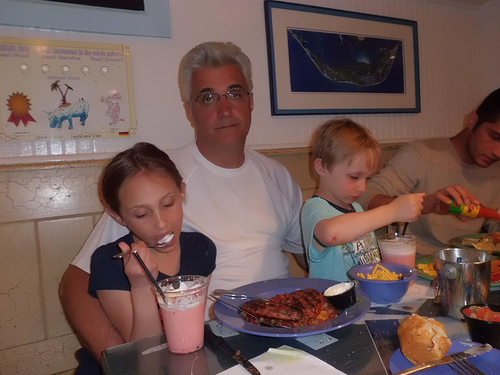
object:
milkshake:
[151, 274, 209, 356]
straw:
[133, 250, 168, 302]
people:
[86, 141, 216, 346]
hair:
[177, 40, 253, 105]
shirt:
[67, 137, 306, 323]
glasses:
[189, 88, 251, 107]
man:
[58, 41, 310, 375]